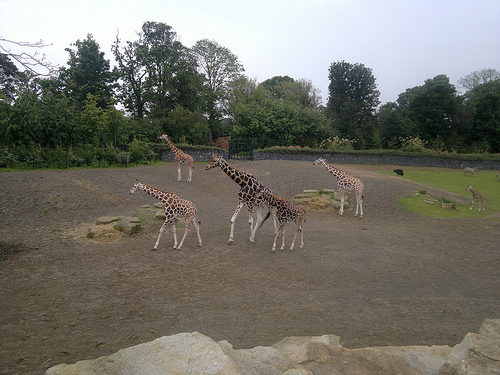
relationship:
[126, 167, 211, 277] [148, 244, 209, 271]
giraffe on dirt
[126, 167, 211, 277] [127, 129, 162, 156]
giraffe on grass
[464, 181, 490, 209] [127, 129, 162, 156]
zebra on grass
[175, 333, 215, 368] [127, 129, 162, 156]
rock and grass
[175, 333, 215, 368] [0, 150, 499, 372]
rock outside pen